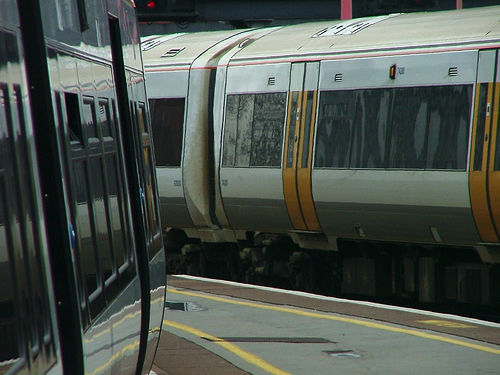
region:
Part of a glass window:
[398, 86, 471, 176]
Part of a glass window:
[342, 88, 422, 186]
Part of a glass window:
[319, 85, 361, 175]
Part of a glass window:
[251, 90, 289, 179]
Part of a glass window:
[220, 90, 264, 177]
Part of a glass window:
[145, 95, 187, 178]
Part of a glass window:
[67, 80, 148, 319]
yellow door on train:
[283, 79, 301, 231]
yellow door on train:
[294, 69, 321, 244]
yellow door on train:
[473, 80, 490, 250]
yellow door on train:
[488, 89, 498, 232]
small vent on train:
[263, 76, 281, 95]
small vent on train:
[328, 69, 350, 95]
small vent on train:
[438, 64, 463, 85]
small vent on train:
[160, 39, 182, 69]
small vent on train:
[170, 179, 187, 193]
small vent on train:
[219, 169, 238, 196]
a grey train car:
[143, 8, 490, 300]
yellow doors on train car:
[270, 68, 356, 251]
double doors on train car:
[255, 36, 356, 287]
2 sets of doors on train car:
[249, 28, 496, 294]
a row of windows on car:
[213, 72, 485, 187]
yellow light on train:
[369, 45, 411, 94]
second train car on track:
[116, 17, 246, 285]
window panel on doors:
[282, 68, 320, 193]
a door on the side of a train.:
[279, 91, 307, 236]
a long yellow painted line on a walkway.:
[166, 288, 499, 357]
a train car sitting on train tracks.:
[214, 0, 497, 321]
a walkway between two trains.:
[149, 269, 499, 374]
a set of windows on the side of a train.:
[55, 91, 129, 317]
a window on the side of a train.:
[249, 96, 285, 171]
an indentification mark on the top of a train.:
[312, 10, 397, 50]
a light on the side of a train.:
[388, 63, 398, 78]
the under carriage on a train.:
[222, 223, 494, 320]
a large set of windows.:
[51, 80, 133, 330]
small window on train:
[65, 91, 90, 146]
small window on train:
[81, 96, 102, 146]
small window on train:
[97, 96, 116, 140]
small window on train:
[138, 98, 150, 134]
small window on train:
[318, 85, 352, 172]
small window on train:
[356, 93, 395, 176]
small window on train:
[388, 85, 427, 174]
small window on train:
[433, 87, 468, 177]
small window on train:
[250, 96, 281, 185]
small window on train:
[222, 104, 262, 176]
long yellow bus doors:
[282, 68, 321, 230]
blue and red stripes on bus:
[222, 51, 486, 68]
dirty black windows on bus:
[212, 100, 293, 181]